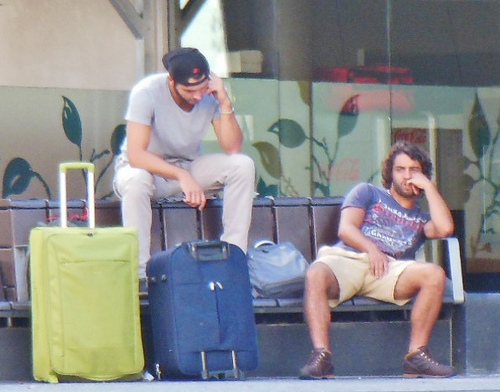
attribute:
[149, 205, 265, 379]
suitcase — blue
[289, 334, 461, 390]
shoes — brown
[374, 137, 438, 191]
hair — dark brown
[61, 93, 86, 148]
leave — green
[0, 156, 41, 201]
leave — green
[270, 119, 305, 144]
leave — green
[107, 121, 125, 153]
leave — green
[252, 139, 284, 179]
leave — green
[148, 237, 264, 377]
luggage — large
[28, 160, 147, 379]
luggage — large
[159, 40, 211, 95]
cap — backwards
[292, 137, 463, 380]
man — seated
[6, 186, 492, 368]
bench — long, metal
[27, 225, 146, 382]
suitcase — yellow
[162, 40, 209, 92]
cap — black, backward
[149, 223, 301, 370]
suitcase — yellow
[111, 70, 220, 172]
shirt — white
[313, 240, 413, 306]
shorts — yellow, light colored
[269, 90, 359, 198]
leaves — green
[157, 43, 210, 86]
cap — baseball